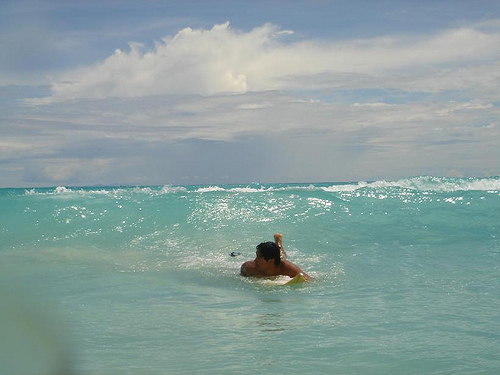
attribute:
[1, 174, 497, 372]
water — blue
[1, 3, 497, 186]
sky — blue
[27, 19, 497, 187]
clouds — white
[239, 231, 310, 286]
man — lying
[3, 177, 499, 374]
ocean — blue, green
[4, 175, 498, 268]
waves — white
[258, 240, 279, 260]
hair — brown, dark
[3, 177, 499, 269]
wave — white